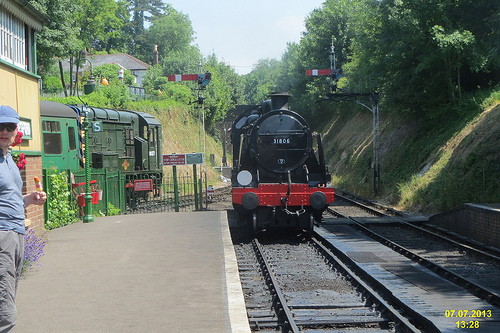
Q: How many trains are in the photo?
A: 2.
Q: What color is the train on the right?
A: Black with a red bumper.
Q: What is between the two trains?
A: A platform.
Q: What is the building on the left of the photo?
A: Train station.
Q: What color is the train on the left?
A: Green.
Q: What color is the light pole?
A: Green.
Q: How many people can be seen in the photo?
A: 1.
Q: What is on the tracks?
A: A train.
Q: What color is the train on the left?
A: Green and black.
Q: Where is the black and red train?
A: On the tracks.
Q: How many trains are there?
A: 2.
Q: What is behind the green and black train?
A: A house.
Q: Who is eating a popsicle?
A: A tourist.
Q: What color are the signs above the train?
A: Red and white.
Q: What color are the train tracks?
A: Black.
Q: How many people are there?
A: 1.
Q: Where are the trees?
A: Both sides of the road.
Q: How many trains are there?
A: 1.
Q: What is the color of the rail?
A: Green.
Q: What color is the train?
A: Black.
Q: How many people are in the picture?
A: One.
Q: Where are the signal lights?
A: Above the train.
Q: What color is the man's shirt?
A: Blue.